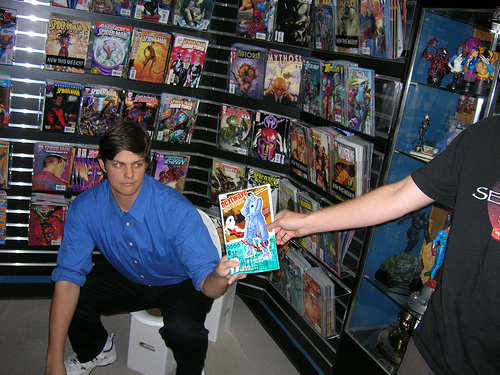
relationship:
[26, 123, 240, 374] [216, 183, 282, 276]
boy holding magazine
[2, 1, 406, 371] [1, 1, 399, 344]
racks of comic books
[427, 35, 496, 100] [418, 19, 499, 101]
figurines on shelf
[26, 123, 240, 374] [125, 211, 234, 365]
man on toilet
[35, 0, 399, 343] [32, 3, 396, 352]
magazines on display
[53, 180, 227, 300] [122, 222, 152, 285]
shirt has buttons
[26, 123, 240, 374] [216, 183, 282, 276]
man holding comic book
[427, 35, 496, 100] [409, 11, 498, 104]
figures on display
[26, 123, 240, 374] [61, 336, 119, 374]
man has sneakers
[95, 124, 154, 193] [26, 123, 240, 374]
face of man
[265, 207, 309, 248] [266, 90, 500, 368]
hand of man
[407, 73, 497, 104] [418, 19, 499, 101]
part of shelf